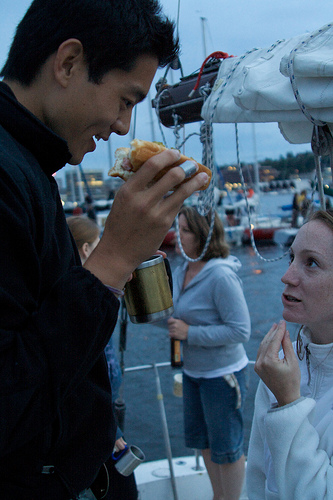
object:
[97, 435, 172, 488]
mug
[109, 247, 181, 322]
thermos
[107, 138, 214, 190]
sandwich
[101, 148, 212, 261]
hand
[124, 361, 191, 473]
railing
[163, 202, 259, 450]
lady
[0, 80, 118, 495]
black fleece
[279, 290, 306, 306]
mouth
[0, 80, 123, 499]
jacket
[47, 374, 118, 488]
pockets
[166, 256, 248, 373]
blue jacke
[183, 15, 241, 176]
pole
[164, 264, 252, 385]
jacket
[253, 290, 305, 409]
sign language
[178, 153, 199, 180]
ring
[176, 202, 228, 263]
brown hair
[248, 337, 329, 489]
white jacket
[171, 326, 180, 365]
beer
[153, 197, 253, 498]
woman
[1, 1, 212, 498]
man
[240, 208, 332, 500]
woman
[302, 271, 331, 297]
freckles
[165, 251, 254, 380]
coat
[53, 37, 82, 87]
left ear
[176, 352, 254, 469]
jeans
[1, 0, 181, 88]
hair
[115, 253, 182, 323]
cup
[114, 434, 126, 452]
hand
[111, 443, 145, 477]
cup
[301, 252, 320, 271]
right eye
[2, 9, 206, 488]
young man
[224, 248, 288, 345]
water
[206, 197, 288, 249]
boat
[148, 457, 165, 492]
white boat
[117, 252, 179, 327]
mug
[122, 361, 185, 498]
rail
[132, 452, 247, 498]
boat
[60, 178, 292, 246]
dock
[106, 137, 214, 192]
bun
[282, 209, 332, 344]
face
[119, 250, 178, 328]
coffee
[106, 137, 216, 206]
food